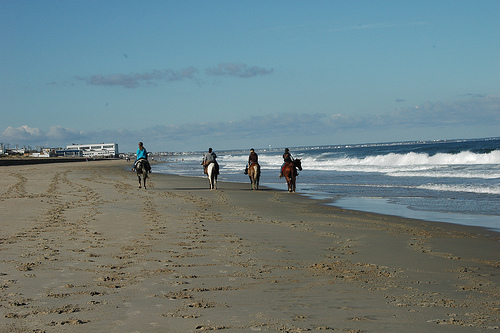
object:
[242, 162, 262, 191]
horses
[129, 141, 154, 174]
people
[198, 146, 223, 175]
rider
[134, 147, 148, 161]
jacket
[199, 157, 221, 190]
horse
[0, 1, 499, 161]
away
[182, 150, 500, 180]
waves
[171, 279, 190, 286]
hoofprints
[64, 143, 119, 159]
building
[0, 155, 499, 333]
beach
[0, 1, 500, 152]
sky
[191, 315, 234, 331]
footprints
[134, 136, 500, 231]
surf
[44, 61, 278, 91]
clouds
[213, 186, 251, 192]
shadow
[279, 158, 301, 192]
horse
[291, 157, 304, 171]
head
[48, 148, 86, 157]
buildings